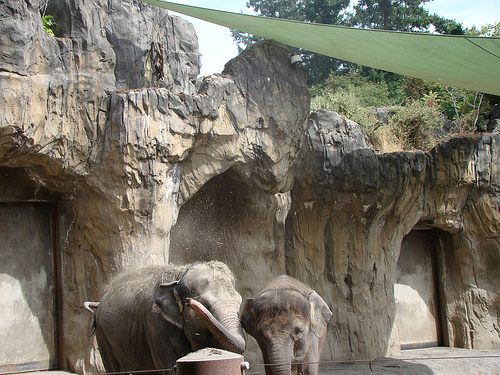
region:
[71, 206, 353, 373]
two elephants standing together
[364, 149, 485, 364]
a doorway in the rocks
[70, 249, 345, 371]
the elephants are gray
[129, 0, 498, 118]
a green canopy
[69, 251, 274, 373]
the elephant has a long trunk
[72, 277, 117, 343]
the elephant has a tail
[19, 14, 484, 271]
the rocks are brown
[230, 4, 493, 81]
the trees are green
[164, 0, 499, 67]
the sky is blue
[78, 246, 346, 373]
one of the elephants is smaller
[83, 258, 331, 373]
a pair of elephants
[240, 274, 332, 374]
the baby elephant is facing the camera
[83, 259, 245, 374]
the mother elephant waves her trunk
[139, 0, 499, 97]
a green canopy above the elephants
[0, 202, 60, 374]
a metal door behind the elephants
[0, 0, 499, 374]
rock wall behind the elephants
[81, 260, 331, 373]
two elephants eating food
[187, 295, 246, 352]
the big elephant's trunk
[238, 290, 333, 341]
the small elephant's ears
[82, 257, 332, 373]
two elephants are standing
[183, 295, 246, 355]
elephant's trunk is raised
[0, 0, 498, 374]
rock wall behind elephants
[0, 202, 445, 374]
rusty doors behind elephants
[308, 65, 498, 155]
plants over rock wall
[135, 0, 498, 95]
green shelter over elephants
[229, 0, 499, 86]
tree over elephants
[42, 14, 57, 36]
small plant in a notch in the rock wall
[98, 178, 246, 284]
elephant shooting up dust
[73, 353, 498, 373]
fence in front of elephants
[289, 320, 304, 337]
the eye of an elephant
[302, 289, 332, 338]
the ear of an elephant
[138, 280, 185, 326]
the ear of an elephant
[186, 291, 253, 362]
the trunk of an elephant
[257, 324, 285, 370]
the trunk of an elephant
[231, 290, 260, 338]
the ear of an elephant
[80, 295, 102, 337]
the ear of an elephant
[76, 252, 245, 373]
a big elephant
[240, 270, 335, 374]
a small elephant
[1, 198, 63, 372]
a door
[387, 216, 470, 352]
elephant habitat exit door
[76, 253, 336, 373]
two elephants in exhibit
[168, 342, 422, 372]
metal fence post and wire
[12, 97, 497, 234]
cement carved to resemble rocks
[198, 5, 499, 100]
tarp blocking sun from elephants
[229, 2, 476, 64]
trees in the background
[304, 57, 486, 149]
brush above the rocks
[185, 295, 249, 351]
elephants curled up trunk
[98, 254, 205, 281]
elephants hairy back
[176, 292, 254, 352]
elephants trunk blocking his eye